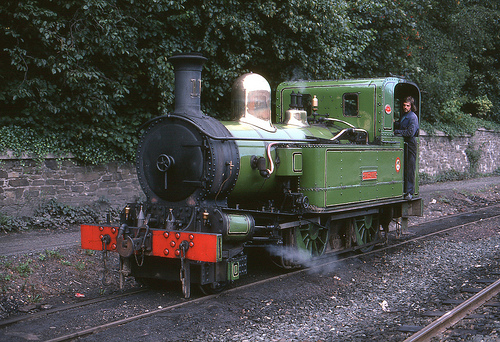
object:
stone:
[11, 179, 117, 210]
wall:
[3, 164, 142, 219]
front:
[128, 100, 225, 277]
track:
[428, 182, 493, 246]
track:
[415, 260, 492, 340]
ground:
[157, 231, 466, 340]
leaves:
[67, 72, 78, 79]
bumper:
[70, 220, 224, 271]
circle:
[135, 116, 204, 202]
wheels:
[347, 227, 385, 253]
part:
[234, 69, 283, 133]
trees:
[69, 52, 98, 162]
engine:
[78, 51, 423, 297]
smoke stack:
[167, 51, 208, 115]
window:
[341, 90, 361, 114]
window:
[291, 88, 314, 110]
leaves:
[51, 19, 67, 28]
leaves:
[123, 47, 136, 56]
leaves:
[201, 45, 211, 53]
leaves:
[282, 35, 293, 43]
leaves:
[392, 37, 397, 46]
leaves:
[433, 56, 444, 64]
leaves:
[430, 80, 439, 93]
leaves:
[438, 95, 446, 102]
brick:
[2, 171, 28, 185]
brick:
[24, 187, 52, 197]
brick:
[70, 183, 95, 192]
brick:
[92, 169, 131, 179]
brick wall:
[0, 150, 144, 232]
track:
[434, 286, 481, 323]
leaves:
[284, 10, 296, 19]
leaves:
[317, 21, 327, 28]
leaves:
[324, 52, 334, 57]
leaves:
[355, 36, 361, 41]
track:
[0, 268, 312, 340]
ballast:
[269, 293, 373, 333]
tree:
[7, 3, 138, 123]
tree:
[145, 0, 262, 84]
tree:
[271, 2, 375, 77]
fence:
[1, 127, 499, 233]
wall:
[2, 120, 499, 235]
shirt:
[397, 110, 420, 138]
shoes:
[404, 192, 415, 200]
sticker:
[151, 231, 191, 264]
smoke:
[256, 233, 349, 283]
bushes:
[6, 1, 496, 181]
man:
[391, 98, 422, 200]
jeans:
[400, 136, 420, 205]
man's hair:
[406, 90, 419, 114]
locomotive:
[80, 52, 421, 298]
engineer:
[388, 92, 422, 202]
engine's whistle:
[285, 88, 313, 133]